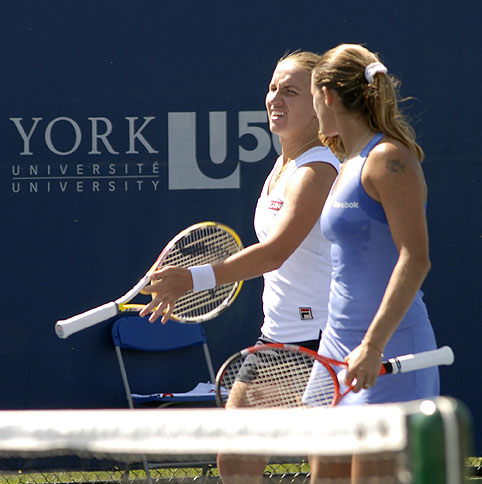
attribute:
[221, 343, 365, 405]
tennis racket — red